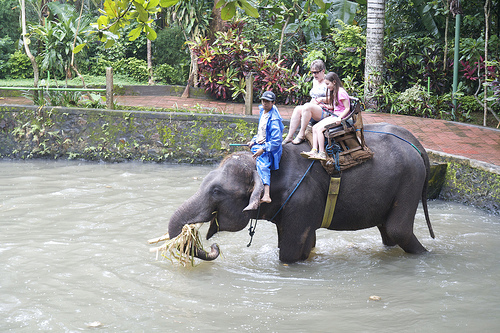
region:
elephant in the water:
[117, 78, 431, 305]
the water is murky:
[43, 186, 164, 328]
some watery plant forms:
[152, 224, 202, 266]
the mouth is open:
[202, 214, 219, 239]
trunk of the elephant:
[167, 194, 219, 261]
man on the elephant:
[230, 91, 281, 211]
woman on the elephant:
[285, 59, 327, 144]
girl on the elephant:
[304, 74, 348, 160]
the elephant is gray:
[150, 123, 434, 264]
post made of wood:
[104, 69, 112, 108]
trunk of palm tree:
[364, 1, 381, 99]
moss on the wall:
[156, 124, 179, 145]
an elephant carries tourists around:
[150, 55, 441, 283]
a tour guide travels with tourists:
[172, 48, 454, 269]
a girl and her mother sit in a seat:
[277, 54, 371, 166]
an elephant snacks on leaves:
[163, 133, 258, 277]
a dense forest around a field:
[3, 3, 497, 118]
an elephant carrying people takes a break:
[153, 50, 471, 261]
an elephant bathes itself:
[153, 124, 441, 275]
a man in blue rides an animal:
[236, 81, 287, 208]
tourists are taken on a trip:
[227, 51, 375, 226]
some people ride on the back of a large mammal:
[149, 55, 449, 272]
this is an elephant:
[141, 102, 465, 287]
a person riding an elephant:
[212, 33, 284, 213]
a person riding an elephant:
[272, 48, 340, 140]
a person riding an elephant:
[301, 78, 362, 166]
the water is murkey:
[134, 281, 188, 318]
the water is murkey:
[317, 251, 418, 322]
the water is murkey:
[5, 186, 122, 273]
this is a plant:
[18, 11, 78, 81]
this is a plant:
[50, 5, 122, 77]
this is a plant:
[188, 36, 272, 107]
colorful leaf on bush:
[192, 54, 208, 69]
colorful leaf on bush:
[258, 59, 274, 84]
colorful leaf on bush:
[276, 74, 289, 93]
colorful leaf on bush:
[262, 52, 278, 69]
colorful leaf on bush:
[201, 67, 215, 89]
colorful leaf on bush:
[211, 83, 229, 101]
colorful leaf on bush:
[265, 74, 287, 91]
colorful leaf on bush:
[206, 38, 231, 67]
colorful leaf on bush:
[204, 61, 228, 81]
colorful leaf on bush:
[248, 40, 272, 69]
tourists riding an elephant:
[289, 55, 348, 162]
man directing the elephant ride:
[244, 85, 284, 217]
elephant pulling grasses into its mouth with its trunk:
[163, 200, 233, 281]